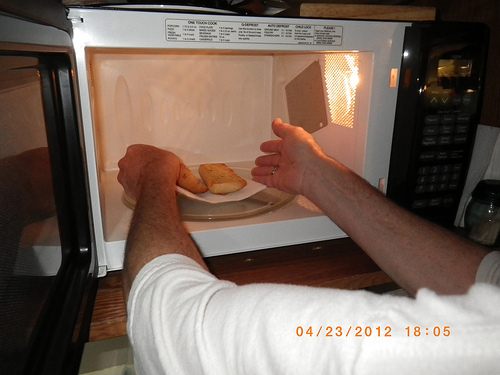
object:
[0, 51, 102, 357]
glass door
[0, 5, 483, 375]
black microwave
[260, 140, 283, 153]
finger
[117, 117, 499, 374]
man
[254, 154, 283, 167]
finger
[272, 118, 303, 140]
finger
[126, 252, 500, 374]
sleeve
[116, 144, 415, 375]
arm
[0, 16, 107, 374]
door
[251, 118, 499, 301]
arms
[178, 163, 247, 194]
food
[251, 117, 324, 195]
hand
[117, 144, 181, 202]
hand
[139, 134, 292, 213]
food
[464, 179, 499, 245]
container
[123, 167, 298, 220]
glass plate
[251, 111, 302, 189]
finger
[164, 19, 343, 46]
instruction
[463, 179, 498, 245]
jar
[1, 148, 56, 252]
reflection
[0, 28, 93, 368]
surface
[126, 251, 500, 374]
shirt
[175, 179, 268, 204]
napkin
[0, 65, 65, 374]
window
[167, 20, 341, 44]
words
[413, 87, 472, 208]
buttons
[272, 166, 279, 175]
ring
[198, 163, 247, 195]
hot pocket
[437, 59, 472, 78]
display screen